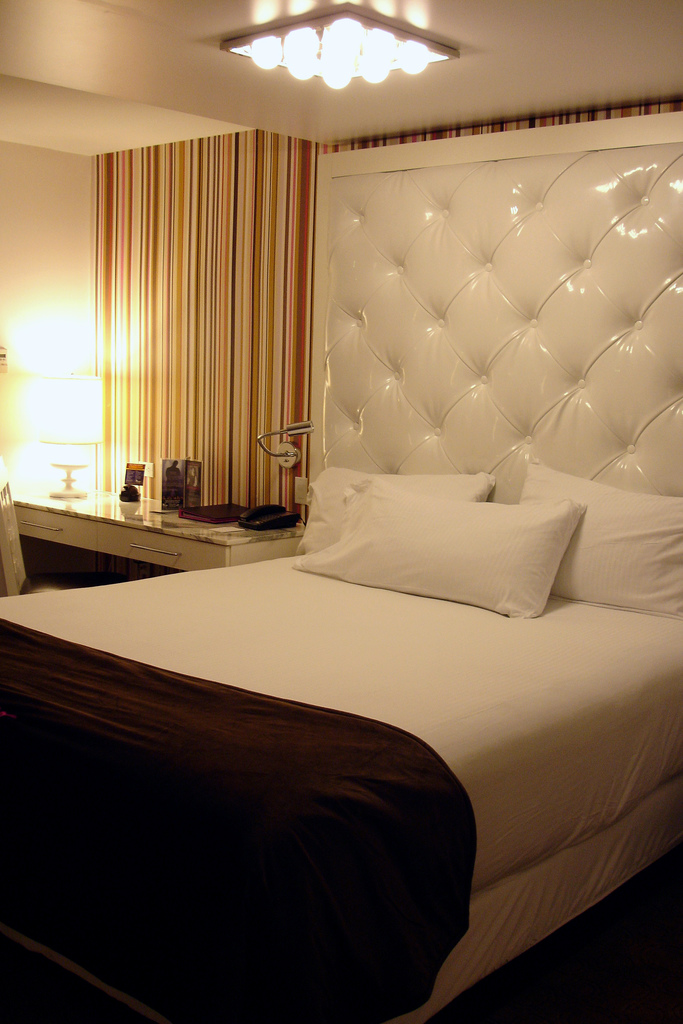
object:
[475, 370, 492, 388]
button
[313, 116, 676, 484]
board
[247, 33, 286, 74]
lightbulbs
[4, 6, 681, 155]
ceiling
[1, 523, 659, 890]
sheets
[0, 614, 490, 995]
comforter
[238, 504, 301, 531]
phone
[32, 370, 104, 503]
lamp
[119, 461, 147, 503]
frame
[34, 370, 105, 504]
table lamp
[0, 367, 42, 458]
shade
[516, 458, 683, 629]
pillow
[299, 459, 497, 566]
pillow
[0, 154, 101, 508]
wall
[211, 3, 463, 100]
light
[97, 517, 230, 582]
drawer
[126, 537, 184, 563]
handle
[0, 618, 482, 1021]
blanket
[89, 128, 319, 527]
curtain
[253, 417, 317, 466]
lamp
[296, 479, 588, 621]
pillow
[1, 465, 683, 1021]
bed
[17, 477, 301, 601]
desk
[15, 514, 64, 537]
drawer handles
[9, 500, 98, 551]
drawer